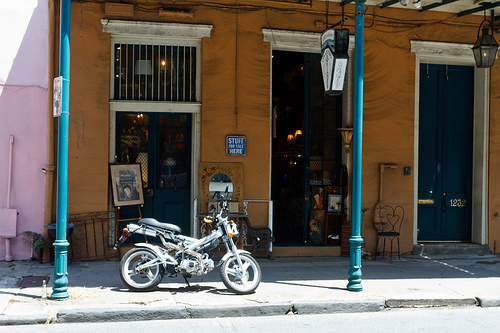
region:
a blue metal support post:
[348, 7, 370, 287]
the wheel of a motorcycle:
[215, 254, 261, 293]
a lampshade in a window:
[131, 55, 156, 77]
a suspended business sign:
[316, 27, 351, 97]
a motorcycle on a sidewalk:
[90, 191, 267, 331]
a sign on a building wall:
[217, 128, 253, 160]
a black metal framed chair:
[374, 200, 406, 255]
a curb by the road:
[123, 300, 325, 320]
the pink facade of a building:
[16, 92, 41, 134]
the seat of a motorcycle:
[138, 215, 180, 235]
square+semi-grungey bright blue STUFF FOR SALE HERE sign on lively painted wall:
[223, 132, 245, 157]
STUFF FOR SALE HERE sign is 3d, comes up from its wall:
[223, 130, 249, 157]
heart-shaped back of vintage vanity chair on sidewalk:
[366, 196, 406, 261]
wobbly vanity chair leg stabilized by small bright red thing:
[377, 253, 387, 259]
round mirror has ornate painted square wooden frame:
[195, 160, 241, 215]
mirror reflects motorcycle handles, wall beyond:
[205, 167, 231, 202]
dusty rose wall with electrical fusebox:
[0, 0, 50, 265]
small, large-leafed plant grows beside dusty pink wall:
[15, 225, 47, 265]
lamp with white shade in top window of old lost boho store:
[130, 53, 155, 99]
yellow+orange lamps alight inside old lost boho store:
[283, 125, 303, 144]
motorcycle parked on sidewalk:
[114, 189, 263, 291]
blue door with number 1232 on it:
[417, 60, 474, 245]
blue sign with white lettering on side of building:
[222, 134, 248, 161]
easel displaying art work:
[109, 160, 147, 253]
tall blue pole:
[347, 0, 363, 292]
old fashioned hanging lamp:
[464, 15, 499, 72]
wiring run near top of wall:
[360, 7, 486, 38]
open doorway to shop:
[270, 49, 350, 249]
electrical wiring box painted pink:
[0, 201, 18, 248]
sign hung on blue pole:
[45, 72, 74, 115]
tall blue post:
[49, 0, 75, 315]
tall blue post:
[347, 0, 368, 296]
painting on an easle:
[108, 160, 143, 260]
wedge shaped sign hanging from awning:
[315, 6, 347, 99]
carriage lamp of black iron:
[467, 12, 497, 75]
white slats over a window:
[105, 1, 205, 106]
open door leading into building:
[265, 29, 348, 254]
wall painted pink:
[0, 2, 48, 273]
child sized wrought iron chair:
[371, 202, 407, 256]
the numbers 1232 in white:
[445, 192, 477, 212]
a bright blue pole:
[345, 50, 369, 288]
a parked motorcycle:
[118, 184, 264, 307]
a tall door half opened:
[271, 45, 352, 252]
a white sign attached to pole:
[43, 61, 76, 128]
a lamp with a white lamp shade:
[126, 52, 163, 100]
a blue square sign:
[223, 128, 252, 158]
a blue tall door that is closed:
[420, 55, 487, 257]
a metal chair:
[374, 201, 406, 261]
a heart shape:
[376, 201, 408, 233]